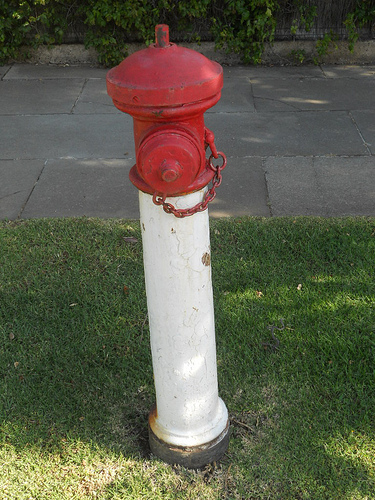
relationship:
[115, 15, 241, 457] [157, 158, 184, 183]
hydrant has bolt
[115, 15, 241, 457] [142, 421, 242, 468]
hydrant has base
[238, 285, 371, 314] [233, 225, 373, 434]
light in grass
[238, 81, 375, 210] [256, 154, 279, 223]
cement has crack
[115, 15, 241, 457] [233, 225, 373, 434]
hydrant in grass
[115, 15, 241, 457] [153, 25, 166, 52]
hydrant has rust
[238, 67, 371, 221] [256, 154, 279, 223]
sidewalk has crack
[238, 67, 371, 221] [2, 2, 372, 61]
sidewalk has bushes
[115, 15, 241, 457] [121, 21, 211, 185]
hydrant missing paint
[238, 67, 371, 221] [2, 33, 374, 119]
sidewalk on curb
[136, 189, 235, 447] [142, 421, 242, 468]
post has base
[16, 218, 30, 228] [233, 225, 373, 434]
piece of grass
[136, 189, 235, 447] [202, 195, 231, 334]
post has edge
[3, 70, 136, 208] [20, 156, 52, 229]
concrete has cracks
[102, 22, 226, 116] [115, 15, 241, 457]
top of hydrant